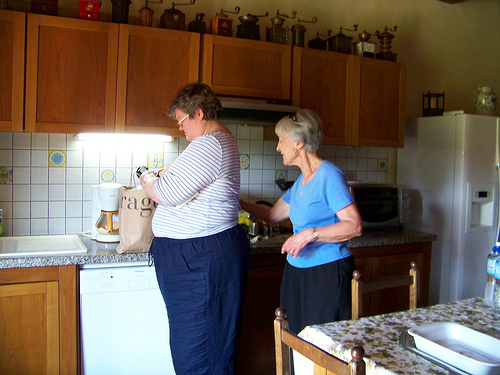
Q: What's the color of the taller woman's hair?
A: Brown.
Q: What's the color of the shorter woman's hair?
A: Gray.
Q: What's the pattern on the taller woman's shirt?
A: Stripes.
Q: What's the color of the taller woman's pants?
A: Blue.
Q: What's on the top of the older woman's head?
A: Sunglasses.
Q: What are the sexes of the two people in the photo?
A: Both female.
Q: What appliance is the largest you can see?
A: Refrigerator.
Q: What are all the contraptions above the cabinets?
A: Pepper mills.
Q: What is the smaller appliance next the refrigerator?
A: Toaster oven.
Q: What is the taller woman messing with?
A: Paper bag.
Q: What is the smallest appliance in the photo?
A: Coffee maker.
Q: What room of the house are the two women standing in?
A: Kitchen.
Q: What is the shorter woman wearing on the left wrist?
A: A watch.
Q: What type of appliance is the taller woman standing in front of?
A: Dishwasher.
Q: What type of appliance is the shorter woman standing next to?
A: Stove/oven.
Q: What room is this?
A: Kitchen.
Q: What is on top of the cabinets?
A: Grinders.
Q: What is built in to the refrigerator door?
A: Ice maker.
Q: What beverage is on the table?
A: Water.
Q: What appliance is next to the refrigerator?
A: Toaster Oven.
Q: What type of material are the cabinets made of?
A: Wood.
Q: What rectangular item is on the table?
A: Baking dish.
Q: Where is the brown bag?
A: On the counter.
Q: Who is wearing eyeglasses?
A: Woman in the striped shirt.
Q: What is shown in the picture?
A: A kitchen.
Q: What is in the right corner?
A: A fridge.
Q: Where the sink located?
A: To the left.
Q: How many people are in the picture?
A: Two.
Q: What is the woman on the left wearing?
A: Blue pants.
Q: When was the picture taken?
A: In the day.